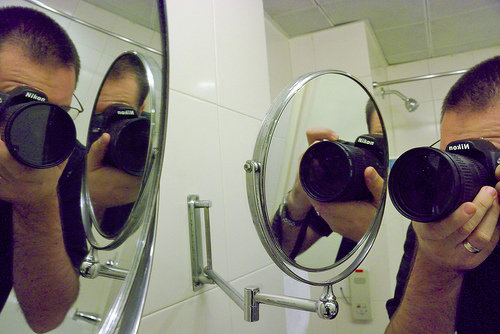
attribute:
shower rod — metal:
[370, 64, 469, 108]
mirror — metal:
[0, 3, 174, 332]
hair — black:
[420, 63, 492, 134]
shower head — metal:
[380, 83, 425, 115]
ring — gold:
[453, 236, 483, 261]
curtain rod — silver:
[368, 62, 470, 99]